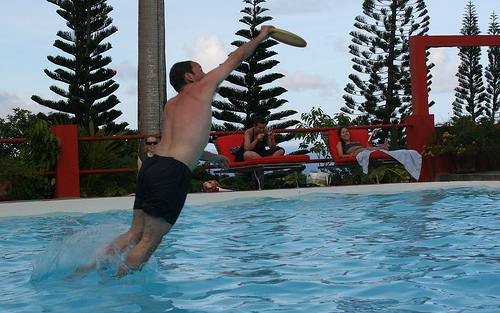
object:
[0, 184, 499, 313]
pool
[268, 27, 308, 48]
frisbee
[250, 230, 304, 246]
ripples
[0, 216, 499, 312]
water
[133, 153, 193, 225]
shorts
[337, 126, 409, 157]
people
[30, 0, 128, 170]
trees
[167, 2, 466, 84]
sky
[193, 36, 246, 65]
clouds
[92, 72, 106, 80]
leaves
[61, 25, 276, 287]
male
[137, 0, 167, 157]
trunks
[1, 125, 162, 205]
fence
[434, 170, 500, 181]
entry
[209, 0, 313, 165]
tree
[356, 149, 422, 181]
towel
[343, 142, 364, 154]
bathing suit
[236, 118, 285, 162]
lady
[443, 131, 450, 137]
flowers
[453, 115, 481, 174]
plant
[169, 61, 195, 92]
hair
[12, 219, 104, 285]
waves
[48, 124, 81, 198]
poles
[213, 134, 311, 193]
chairs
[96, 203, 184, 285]
legs